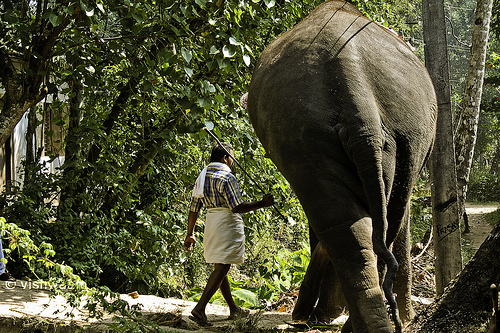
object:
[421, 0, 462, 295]
pole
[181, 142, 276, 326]
man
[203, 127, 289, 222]
stick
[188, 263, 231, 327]
leg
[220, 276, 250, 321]
leg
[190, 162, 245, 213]
plaid shirt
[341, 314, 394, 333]
foot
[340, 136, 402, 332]
tail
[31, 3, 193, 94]
branches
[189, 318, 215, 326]
feet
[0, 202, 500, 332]
ground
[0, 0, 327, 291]
leaves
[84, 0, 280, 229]
trees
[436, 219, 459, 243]
writing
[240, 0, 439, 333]
elephant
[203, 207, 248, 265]
skirt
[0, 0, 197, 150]
tree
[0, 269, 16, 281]
shoe